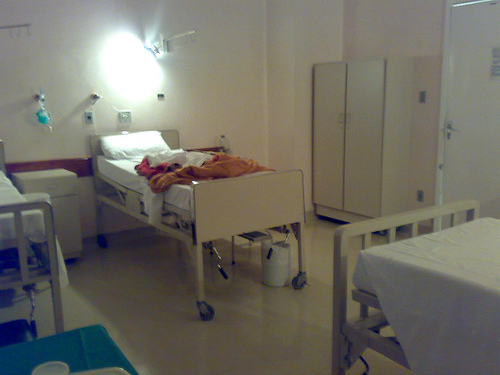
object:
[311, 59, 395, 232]
cabinet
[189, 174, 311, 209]
end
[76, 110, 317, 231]
bed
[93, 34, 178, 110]
circle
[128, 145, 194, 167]
clothes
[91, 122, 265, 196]
view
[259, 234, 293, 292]
object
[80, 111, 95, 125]
object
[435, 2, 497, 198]
door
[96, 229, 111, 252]
wheel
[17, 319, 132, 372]
cloth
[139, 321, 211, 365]
floor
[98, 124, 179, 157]
pillow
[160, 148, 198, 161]
sheet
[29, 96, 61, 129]
iv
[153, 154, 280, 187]
blanket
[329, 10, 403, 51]
area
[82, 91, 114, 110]
stand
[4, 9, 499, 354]
room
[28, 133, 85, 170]
left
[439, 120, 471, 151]
lever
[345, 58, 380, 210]
doors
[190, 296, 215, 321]
foot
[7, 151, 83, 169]
stripe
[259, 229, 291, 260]
footstool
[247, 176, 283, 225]
to bed